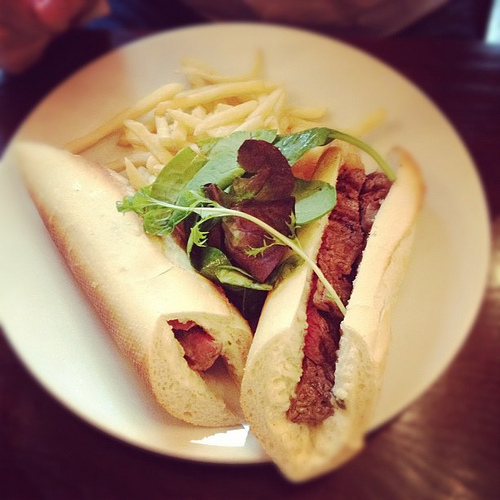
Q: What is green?
A: Arugula.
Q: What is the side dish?
A: Fries.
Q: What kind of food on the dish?
A: Sandwich.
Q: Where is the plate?
A: On the table.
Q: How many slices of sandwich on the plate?
A: Two.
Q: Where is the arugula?
A: On top of the sandwich.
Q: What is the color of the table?
A: Brown.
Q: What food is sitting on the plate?
A: Sandwich, salad, and french fries.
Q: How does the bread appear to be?
A: Tan and fluffy.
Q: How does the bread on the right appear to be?
A: Tan and fluffy.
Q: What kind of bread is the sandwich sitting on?
A: Tan and fluffy.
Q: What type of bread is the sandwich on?
A: Tan and fluffy.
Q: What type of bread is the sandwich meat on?
A: Tan and fluffy.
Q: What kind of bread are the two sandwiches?
A: Tan and fluffy.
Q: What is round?
A: Plate.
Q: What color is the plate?
A: White.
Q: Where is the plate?
A: On a table.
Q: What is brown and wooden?
A: The table.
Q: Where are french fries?
A: On the plate.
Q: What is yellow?
A: French fries.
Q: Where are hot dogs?
A: In buns.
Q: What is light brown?
A: Hot dog buns.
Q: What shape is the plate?
A: Round.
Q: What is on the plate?
A: Food.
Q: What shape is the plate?
A: Round.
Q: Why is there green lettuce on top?
A: It is a garnish.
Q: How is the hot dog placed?
A: In a bread roll.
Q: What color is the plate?
A: White.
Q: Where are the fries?
A: On the plate.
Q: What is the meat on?
A: A bun.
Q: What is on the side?
A: Fries.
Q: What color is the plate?
A: White.